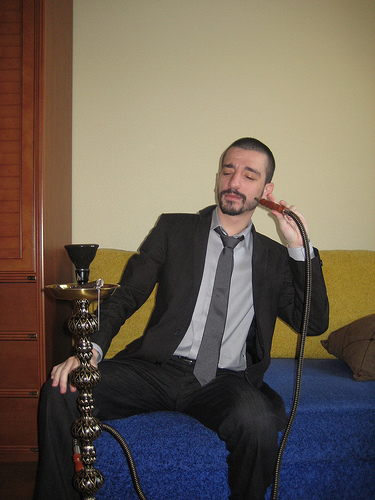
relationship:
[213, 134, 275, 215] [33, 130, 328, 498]
head on man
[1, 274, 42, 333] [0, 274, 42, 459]
drawer in dresser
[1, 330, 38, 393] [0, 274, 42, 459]
drawer in dresser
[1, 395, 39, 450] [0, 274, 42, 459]
drawer in dresser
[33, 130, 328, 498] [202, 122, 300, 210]
man has face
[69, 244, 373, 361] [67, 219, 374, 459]
pillow on side of bed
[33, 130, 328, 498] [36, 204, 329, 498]
man wearing black suit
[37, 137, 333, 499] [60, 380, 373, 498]
man sitting on a bed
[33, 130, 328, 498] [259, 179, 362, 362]
man holding tube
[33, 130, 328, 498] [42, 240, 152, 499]
man holding hookah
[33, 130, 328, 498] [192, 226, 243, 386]
man wearing tie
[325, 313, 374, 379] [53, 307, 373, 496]
pillow on top of bed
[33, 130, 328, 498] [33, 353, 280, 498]
man wearing pants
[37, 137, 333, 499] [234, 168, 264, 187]
man has eyes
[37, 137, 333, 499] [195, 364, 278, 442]
man wearing pants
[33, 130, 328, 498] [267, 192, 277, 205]
man has finger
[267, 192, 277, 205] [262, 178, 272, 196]
finger on ear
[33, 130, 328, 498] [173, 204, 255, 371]
man wearing shirt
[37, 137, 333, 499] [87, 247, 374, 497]
man sitting on sofa